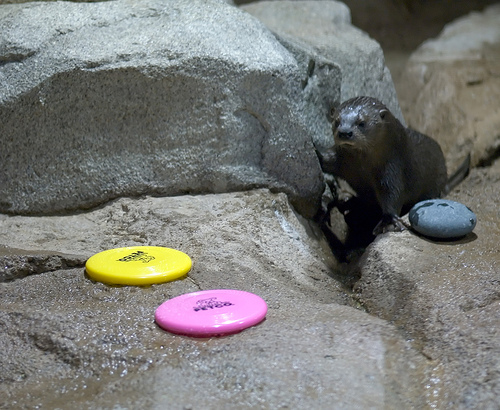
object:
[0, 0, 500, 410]
rock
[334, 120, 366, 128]
eyes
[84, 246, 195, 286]
frisbee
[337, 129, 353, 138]
nose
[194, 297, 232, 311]
graphic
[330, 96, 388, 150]
head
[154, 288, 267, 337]
frisbee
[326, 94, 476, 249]
otter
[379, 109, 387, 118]
ear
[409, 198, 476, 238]
rock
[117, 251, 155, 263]
graphics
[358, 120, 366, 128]
eye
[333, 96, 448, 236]
animal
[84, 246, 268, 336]
frisbees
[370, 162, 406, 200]
fur